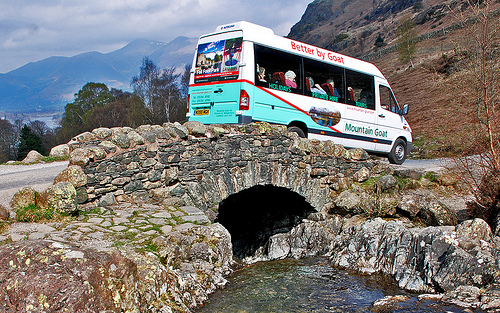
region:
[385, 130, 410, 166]
A round black tire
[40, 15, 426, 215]
A vehicle crossing over a bridge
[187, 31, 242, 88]
A sign on back of a vehicle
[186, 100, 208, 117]
A yellow license plate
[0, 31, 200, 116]
Mountains in the far distance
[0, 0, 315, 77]
Many clouds in the sky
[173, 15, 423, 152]
bus driving over a bridge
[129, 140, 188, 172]
rocks along a bridge and road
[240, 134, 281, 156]
rocks along a bridge and road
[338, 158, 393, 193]
rocks along a bridge and road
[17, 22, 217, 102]
mountains in the distance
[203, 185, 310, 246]
hole in the side of bridge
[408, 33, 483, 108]
brown mountainside of a hill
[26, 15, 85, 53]
cloud sin the sky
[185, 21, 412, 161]
a white and blue tour bus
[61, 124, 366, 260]
a small stone bridge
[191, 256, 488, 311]
a small stream of water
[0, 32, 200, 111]
a mountain range in distance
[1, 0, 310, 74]
an overcast cloudy sky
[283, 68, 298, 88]
a woman passenger on bus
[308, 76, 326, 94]
a passenger on bus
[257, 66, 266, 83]
a passenger on bus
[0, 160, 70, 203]
a paved one lane road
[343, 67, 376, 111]
window on side of passenger van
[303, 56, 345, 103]
window on side of passenger van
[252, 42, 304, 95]
window on side of passenger van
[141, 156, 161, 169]
rock is next to rock on bridge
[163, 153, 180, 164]
rock is next to rock on bridge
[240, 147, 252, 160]
rock is next to rock on bridge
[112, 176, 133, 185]
rock is next to rock on bridge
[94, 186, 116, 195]
rock is next to rock on bridge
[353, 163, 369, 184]
rock is next to rock on bridge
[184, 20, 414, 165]
shuttle buss going over the bridge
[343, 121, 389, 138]
words "Mountain Goat" on the side of the bus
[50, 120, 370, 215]
stone bridge over the stream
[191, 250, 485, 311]
water stream under the bridge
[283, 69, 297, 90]
old woman in a pink top riding in the bus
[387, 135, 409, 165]
front left wheel of the bus